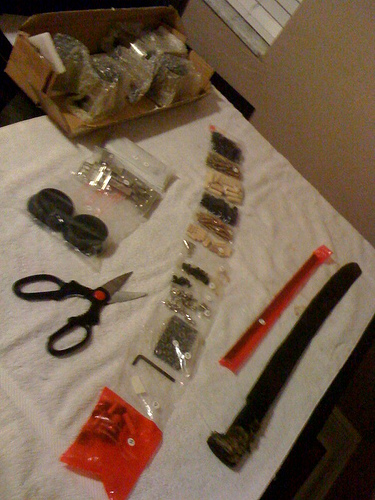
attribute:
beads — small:
[161, 330, 213, 358]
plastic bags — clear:
[108, 351, 183, 413]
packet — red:
[50, 387, 194, 498]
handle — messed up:
[189, 414, 287, 467]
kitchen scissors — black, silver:
[14, 266, 136, 353]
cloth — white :
[243, 155, 322, 257]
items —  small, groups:
[48, 22, 195, 104]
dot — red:
[93, 285, 105, 302]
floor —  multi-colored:
[277, 121, 363, 197]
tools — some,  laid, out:
[27, 128, 354, 489]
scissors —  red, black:
[2, 266, 143, 361]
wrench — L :
[130, 354, 180, 394]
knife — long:
[198, 254, 357, 487]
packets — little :
[130, 134, 249, 387]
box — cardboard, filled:
[17, 2, 211, 126]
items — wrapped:
[53, 29, 194, 94]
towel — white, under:
[10, 106, 361, 490]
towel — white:
[1, 84, 369, 495]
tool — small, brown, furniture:
[129, 352, 177, 387]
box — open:
[2, 4, 216, 141]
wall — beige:
[182, 3, 372, 237]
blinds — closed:
[204, 2, 304, 60]